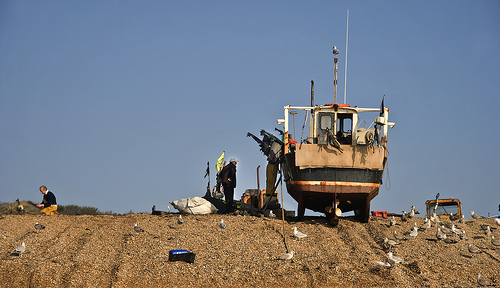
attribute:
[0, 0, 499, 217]
sky — Blue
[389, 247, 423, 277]
bird — Grey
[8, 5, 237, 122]
sky — Blue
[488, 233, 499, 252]
bird — White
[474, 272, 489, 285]
bird — Grey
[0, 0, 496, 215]
blue sky — clear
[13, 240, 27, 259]
bird — Grey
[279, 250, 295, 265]
bird — Grey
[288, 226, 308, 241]
bird — Grey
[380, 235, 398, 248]
bird — Grey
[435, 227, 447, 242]
bird — Grey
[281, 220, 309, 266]
bird — Grey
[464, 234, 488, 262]
bird — Grey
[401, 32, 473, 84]
sky — Blue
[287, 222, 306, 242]
bird — Grey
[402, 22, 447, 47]
clouds — white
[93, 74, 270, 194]
clouds — white